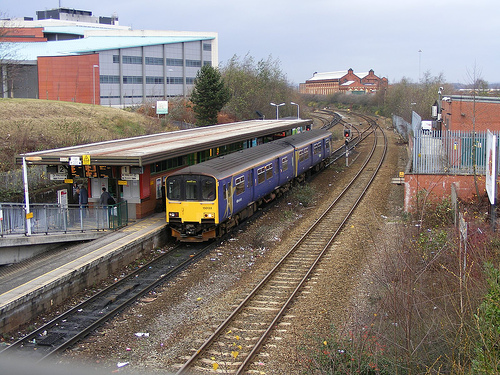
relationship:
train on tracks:
[165, 128, 335, 248] [13, 123, 392, 374]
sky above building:
[4, 5, 499, 80] [3, 11, 223, 110]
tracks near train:
[13, 123, 392, 374] [165, 128, 335, 248]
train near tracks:
[165, 128, 335, 248] [13, 123, 392, 374]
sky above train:
[4, 5, 499, 80] [165, 128, 335, 248]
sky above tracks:
[4, 5, 499, 80] [13, 123, 392, 374]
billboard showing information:
[51, 158, 121, 184] [46, 159, 121, 181]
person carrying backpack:
[94, 184, 117, 222] [104, 197, 112, 215]